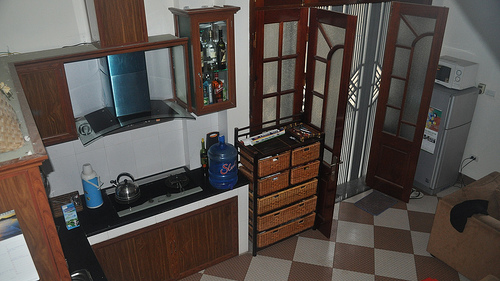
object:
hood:
[73, 99, 196, 148]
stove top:
[96, 165, 208, 218]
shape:
[203, 250, 256, 280]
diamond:
[402, 191, 444, 215]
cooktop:
[55, 165, 253, 238]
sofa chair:
[425, 170, 499, 281]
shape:
[296, 215, 339, 242]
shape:
[287, 260, 335, 280]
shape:
[330, 241, 375, 275]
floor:
[180, 185, 469, 281]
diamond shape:
[371, 222, 414, 254]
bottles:
[208, 73, 225, 106]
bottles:
[202, 135, 242, 191]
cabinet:
[166, 4, 240, 118]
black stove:
[98, 166, 205, 219]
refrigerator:
[405, 86, 480, 196]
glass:
[305, 94, 321, 128]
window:
[260, 60, 278, 95]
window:
[317, 44, 346, 153]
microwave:
[432, 55, 480, 93]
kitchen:
[0, 1, 498, 281]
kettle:
[108, 172, 140, 202]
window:
[306, 94, 327, 126]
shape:
[413, 254, 461, 281]